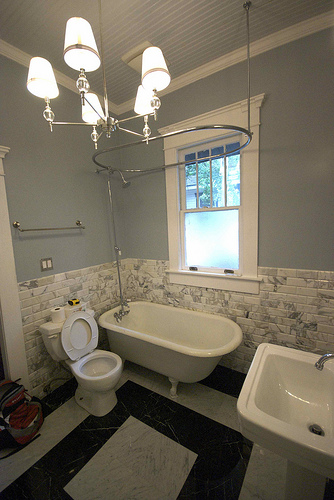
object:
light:
[25, 54, 60, 102]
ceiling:
[0, 0, 334, 107]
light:
[62, 15, 101, 74]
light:
[81, 91, 105, 124]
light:
[133, 82, 160, 116]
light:
[140, 45, 172, 92]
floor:
[1, 359, 334, 500]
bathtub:
[97, 298, 244, 396]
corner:
[115, 104, 132, 299]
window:
[156, 92, 265, 296]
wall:
[117, 30, 334, 376]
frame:
[156, 92, 266, 296]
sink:
[235, 341, 334, 499]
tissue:
[50, 306, 65, 324]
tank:
[38, 308, 97, 364]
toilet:
[39, 306, 124, 419]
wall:
[0, 52, 129, 404]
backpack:
[0, 379, 45, 446]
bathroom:
[0, 0, 334, 498]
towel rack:
[12, 219, 86, 234]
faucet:
[314, 347, 334, 374]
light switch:
[40, 256, 52, 272]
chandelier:
[26, 0, 173, 152]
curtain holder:
[91, 122, 254, 174]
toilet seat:
[60, 310, 99, 363]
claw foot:
[169, 377, 180, 399]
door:
[0, 146, 34, 399]